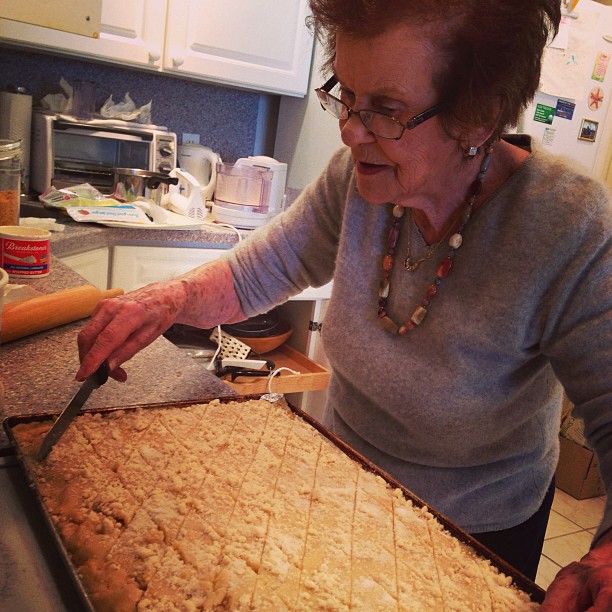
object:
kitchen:
[0, 0, 612, 612]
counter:
[57, 245, 334, 301]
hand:
[75, 281, 179, 382]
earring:
[469, 147, 477, 155]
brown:
[0, 284, 127, 342]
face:
[333, 25, 459, 202]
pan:
[2, 391, 547, 611]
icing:
[0, 226, 48, 235]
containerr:
[0, 226, 51, 279]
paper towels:
[19, 217, 65, 231]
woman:
[75, 0, 612, 611]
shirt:
[222, 134, 612, 532]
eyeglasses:
[315, 74, 447, 139]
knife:
[38, 360, 108, 463]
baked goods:
[12, 398, 541, 612]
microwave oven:
[30, 112, 177, 195]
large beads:
[379, 139, 497, 335]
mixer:
[160, 168, 207, 219]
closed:
[0, 0, 314, 99]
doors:
[0, 0, 316, 98]